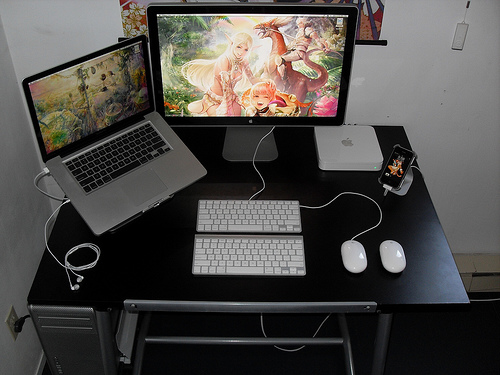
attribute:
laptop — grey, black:
[23, 34, 207, 233]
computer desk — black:
[28, 113, 469, 366]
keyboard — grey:
[196, 198, 305, 232]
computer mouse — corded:
[343, 242, 365, 267]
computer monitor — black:
[146, 10, 352, 122]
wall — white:
[359, 52, 500, 114]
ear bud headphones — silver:
[60, 240, 106, 290]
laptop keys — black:
[67, 121, 174, 193]